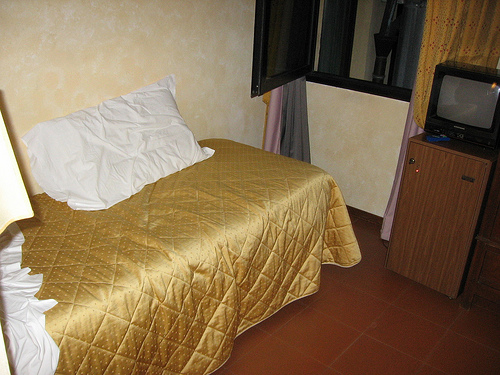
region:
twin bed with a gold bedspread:
[2, 133, 368, 374]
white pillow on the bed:
[19, 69, 216, 213]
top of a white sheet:
[1, 219, 66, 374]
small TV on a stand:
[422, 57, 499, 149]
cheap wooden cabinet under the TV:
[378, 132, 498, 301]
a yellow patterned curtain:
[412, 2, 498, 129]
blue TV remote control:
[422, 130, 451, 147]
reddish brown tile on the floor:
[211, 198, 499, 373]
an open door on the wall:
[248, 0, 418, 102]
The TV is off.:
[426, 52, 494, 154]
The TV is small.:
[429, 56, 494, 153]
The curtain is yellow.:
[324, 0, 496, 134]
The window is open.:
[248, 2, 421, 103]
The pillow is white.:
[21, 77, 257, 189]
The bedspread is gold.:
[52, 135, 360, 356]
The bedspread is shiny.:
[112, 195, 252, 319]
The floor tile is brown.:
[367, 295, 444, 359]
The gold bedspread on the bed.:
[88, 210, 332, 290]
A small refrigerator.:
[389, 133, 466, 290]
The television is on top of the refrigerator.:
[425, 74, 498, 136]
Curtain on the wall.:
[264, 84, 317, 159]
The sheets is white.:
[6, 253, 46, 352]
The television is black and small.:
[423, 55, 492, 135]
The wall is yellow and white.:
[36, 22, 217, 81]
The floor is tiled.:
[323, 286, 430, 360]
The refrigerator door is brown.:
[389, 146, 469, 303]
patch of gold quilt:
[253, 252, 279, 274]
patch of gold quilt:
[185, 298, 214, 319]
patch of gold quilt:
[188, 240, 207, 257]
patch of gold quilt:
[102, 246, 123, 265]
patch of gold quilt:
[238, 189, 260, 212]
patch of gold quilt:
[131, 230, 157, 250]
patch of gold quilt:
[115, 230, 144, 253]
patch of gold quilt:
[174, 188, 206, 210]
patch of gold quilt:
[257, 267, 279, 292]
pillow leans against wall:
[26, 70, 216, 217]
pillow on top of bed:
[23, 72, 218, 214]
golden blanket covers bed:
[0, 138, 360, 373]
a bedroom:
[5, 6, 498, 368]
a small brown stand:
[397, 136, 480, 291]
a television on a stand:
[387, 61, 498, 321]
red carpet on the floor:
[272, 304, 487, 366]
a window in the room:
[319, 11, 415, 82]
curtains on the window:
[411, 13, 496, 60]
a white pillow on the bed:
[26, 104, 223, 201]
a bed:
[6, 171, 317, 373]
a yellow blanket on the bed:
[24, 136, 337, 355]